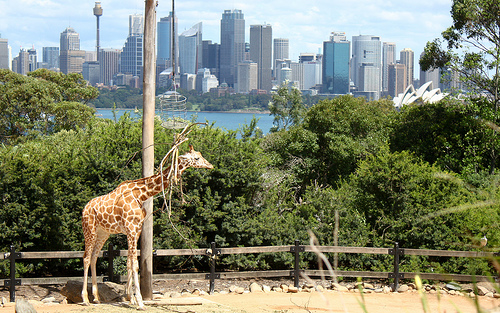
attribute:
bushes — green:
[0, 118, 499, 274]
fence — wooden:
[1, 243, 497, 300]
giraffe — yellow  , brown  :
[80, 145, 212, 309]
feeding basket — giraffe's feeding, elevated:
[155, 90, 190, 139]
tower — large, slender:
[87, 3, 110, 75]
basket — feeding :
[116, 241, 242, 305]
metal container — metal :
[156, 97, 206, 133]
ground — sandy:
[2, 290, 499, 312]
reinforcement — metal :
[204, 242, 223, 264]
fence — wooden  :
[225, 235, 359, 281]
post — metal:
[208, 241, 218, 292]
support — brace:
[390, 241, 400, 288]